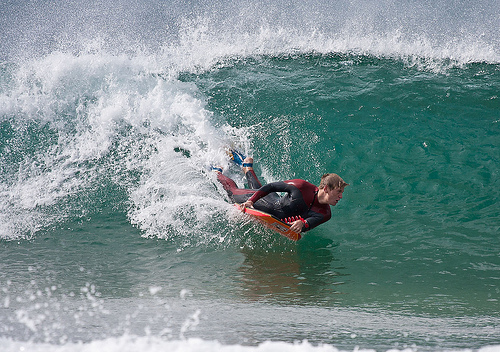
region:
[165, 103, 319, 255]
a man is surfing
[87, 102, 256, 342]
a man is surfing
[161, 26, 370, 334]
a man is surfing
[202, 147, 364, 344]
a man is surfing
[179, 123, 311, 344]
a man is surfing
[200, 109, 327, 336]
a man is surfing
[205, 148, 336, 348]
a man is surfing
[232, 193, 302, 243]
an orange surf board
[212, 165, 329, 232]
a red and black wet suit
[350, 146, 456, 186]
green water in ocean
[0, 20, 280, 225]
white waves in water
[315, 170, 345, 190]
wet brown hair of man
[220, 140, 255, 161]
blue flipper on foot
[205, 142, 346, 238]
surfer surfing in water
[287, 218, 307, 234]
left hand of surfer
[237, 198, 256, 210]
right hand of surfer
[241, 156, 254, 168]
heel of man's foot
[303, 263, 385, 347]
The water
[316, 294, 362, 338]
The water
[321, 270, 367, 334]
The water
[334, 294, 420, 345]
The water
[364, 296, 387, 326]
The water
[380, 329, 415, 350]
The water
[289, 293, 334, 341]
The water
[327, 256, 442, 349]
The water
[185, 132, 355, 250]
male surfer riding a wave on an orange boogie board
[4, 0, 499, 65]
ocean foam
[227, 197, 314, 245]
orange boogie board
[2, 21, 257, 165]
breaking wave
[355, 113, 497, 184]
seafoam green wave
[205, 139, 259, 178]
blue boogie board footstraps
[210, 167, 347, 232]
man in red and black wetsuit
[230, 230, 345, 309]
reflection of man riding boogie board on a wave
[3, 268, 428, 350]
crashing wave near the shore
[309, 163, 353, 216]
man with wet hair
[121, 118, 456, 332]
the man is surfing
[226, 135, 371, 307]
the man is surfing